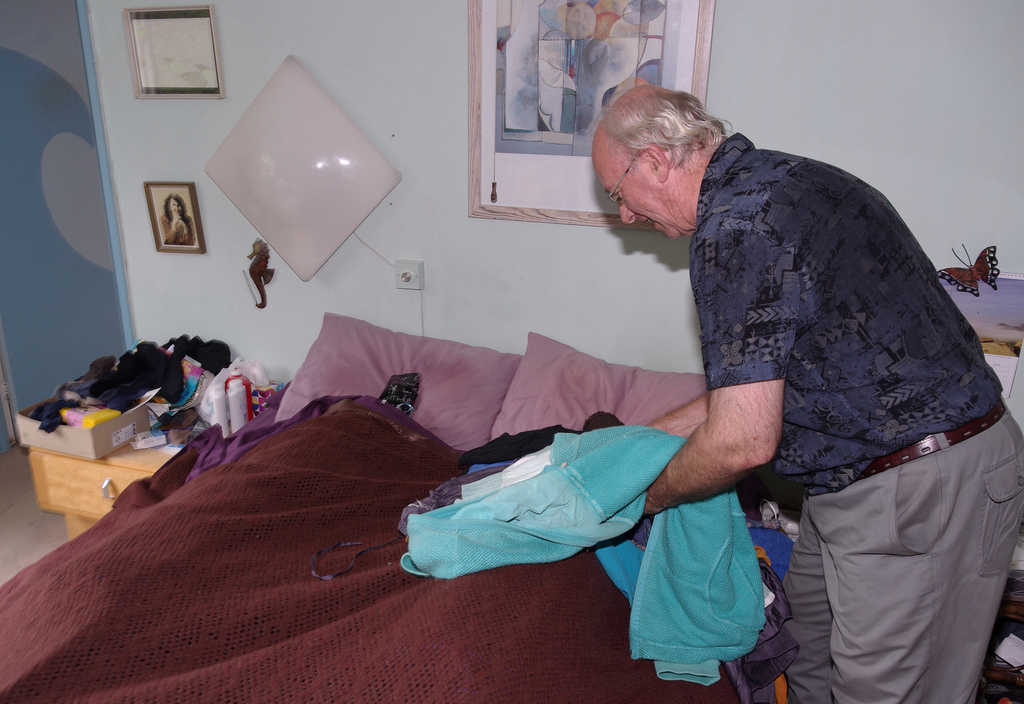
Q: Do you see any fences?
A: No, there are no fences.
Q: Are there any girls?
A: No, there are no girls.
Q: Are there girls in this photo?
A: No, there are no girls.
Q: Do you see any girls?
A: No, there are no girls.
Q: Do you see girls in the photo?
A: No, there are no girls.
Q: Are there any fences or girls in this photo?
A: No, there are no girls or fences.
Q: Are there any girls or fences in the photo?
A: No, there are no girls or fences.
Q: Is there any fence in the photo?
A: No, there are no fences.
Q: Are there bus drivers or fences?
A: No, there are no fences or bus drivers.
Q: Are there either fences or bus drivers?
A: No, there are no fences or bus drivers.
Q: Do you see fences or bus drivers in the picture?
A: No, there are no fences or bus drivers.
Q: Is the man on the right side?
A: Yes, the man is on the right of the image.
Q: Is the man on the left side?
A: No, the man is on the right of the image.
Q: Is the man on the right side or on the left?
A: The man is on the right of the image.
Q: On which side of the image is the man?
A: The man is on the right of the image.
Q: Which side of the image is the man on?
A: The man is on the right of the image.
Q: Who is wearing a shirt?
A: The man is wearing a shirt.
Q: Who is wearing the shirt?
A: The man is wearing a shirt.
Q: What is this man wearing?
A: The man is wearing a shirt.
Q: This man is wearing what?
A: The man is wearing a shirt.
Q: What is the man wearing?
A: The man is wearing a shirt.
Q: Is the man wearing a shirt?
A: Yes, the man is wearing a shirt.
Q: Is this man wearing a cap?
A: No, the man is wearing a shirt.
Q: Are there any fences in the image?
A: No, there are no fences.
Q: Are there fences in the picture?
A: No, there are no fences.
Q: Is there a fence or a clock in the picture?
A: No, there are no fences or clocks.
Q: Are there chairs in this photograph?
A: No, there are no chairs.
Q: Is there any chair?
A: No, there are no chairs.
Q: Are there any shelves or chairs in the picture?
A: No, there are no chairs or shelves.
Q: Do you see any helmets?
A: No, there are no helmets.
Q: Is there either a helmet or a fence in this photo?
A: No, there are no helmets or fences.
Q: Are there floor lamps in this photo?
A: No, there are no floor lamps.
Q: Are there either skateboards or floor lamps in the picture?
A: No, there are no floor lamps or skateboards.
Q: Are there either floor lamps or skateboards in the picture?
A: No, there are no floor lamps or skateboards.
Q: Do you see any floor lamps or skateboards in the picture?
A: No, there are no floor lamps or skateboards.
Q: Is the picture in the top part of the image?
A: Yes, the picture is in the top of the image.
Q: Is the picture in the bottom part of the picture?
A: No, the picture is in the top of the image.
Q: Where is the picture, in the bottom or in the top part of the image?
A: The picture is in the top of the image.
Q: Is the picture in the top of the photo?
A: Yes, the picture is in the top of the image.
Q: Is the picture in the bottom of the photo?
A: No, the picture is in the top of the image.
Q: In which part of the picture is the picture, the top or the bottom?
A: The picture is in the top of the image.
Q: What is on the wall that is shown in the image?
A: The picture is on the wall.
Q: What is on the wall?
A: The picture is on the wall.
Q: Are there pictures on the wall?
A: Yes, there is a picture on the wall.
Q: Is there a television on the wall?
A: No, there is a picture on the wall.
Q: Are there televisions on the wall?
A: No, there is a picture on the wall.